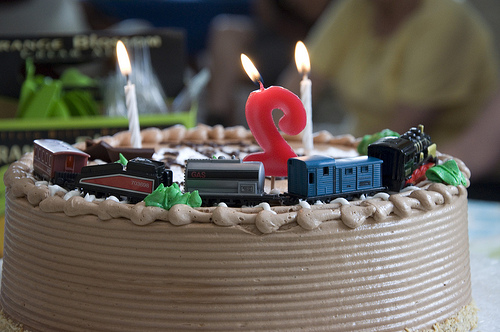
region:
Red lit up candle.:
[235, 53, 310, 175]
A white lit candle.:
[116, 37, 143, 146]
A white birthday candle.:
[293, 37, 313, 154]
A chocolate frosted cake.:
[0, 119, 477, 330]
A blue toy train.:
[286, 148, 386, 201]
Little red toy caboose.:
[29, 139, 91, 183]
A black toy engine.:
[368, 122, 438, 191]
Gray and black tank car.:
[183, 155, 265, 205]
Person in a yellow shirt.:
[305, 1, 496, 136]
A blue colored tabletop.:
[467, 195, 499, 328]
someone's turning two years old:
[237, 59, 307, 179]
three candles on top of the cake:
[114, 40, 325, 179]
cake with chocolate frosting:
[6, 133, 476, 330]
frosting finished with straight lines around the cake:
[5, 135, 475, 330]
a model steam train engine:
[373, 122, 435, 187]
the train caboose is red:
[27, 138, 85, 182]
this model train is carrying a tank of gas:
[184, 158, 266, 204]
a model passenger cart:
[276, 150, 386, 196]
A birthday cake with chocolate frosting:
[70, 96, 375, 274]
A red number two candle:
[234, 54, 304, 181]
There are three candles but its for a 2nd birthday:
[105, 39, 318, 151]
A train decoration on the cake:
[34, 128, 439, 200]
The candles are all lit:
[103, 31, 324, 92]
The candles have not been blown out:
[116, 28, 313, 155]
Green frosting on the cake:
[141, 181, 210, 221]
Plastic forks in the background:
[108, 60, 192, 110]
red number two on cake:
[253, 97, 294, 144]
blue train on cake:
[289, 152, 377, 193]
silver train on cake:
[182, 163, 264, 193]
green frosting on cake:
[144, 187, 201, 206]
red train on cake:
[26, 137, 80, 169]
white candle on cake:
[120, 90, 146, 145]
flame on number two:
[234, 52, 265, 79]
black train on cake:
[381, 139, 428, 175]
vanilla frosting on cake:
[256, 253, 305, 288]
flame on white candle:
[108, 40, 137, 74]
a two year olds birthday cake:
[11, 39, 462, 319]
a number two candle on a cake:
[225, 53, 299, 175]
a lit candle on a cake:
[97, 42, 161, 130]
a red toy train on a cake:
[28, 129, 78, 186]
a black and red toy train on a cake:
[90, 156, 150, 207]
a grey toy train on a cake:
[178, 153, 268, 210]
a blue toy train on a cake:
[290, 149, 388, 206]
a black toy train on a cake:
[362, 123, 437, 174]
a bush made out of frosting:
[147, 185, 198, 216]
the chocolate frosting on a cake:
[137, 233, 302, 317]